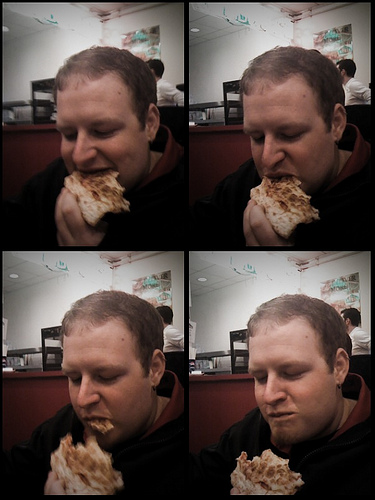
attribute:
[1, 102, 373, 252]
counter — red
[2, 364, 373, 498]
counter — red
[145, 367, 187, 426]
collar — red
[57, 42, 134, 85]
hair — brown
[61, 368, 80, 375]
eyebrow — light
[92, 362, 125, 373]
eyebrow — light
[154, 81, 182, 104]
shirt — white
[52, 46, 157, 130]
hair — short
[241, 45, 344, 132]
hair — short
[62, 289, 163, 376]
hair — short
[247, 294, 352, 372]
hair — short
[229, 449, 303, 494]
bread — brown